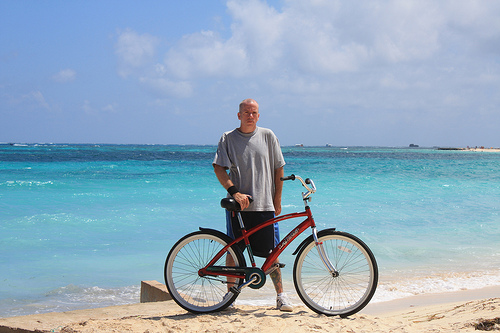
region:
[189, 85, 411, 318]
a man with a bike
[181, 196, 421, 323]
a man with a red bike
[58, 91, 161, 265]
blue bright water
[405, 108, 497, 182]
a island in the backgroudn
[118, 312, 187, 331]
sand on ground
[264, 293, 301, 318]
the shoes for the man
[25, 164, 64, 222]
a little bit of waves in the back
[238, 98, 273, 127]
the man with the bikes face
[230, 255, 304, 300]
the pedals of the bike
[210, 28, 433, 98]
clouds in the back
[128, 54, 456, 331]
man with bicycle at the beach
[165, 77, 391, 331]
white man with bicycle at beach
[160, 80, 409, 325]
blond man with bicycle at beach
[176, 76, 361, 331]
man with red bicycle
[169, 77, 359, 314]
man standing next to bicycle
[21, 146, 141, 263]
beautiful blue ocean water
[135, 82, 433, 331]
riding bicycle on sandy beach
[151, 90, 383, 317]
bicyclist in grey t-shirt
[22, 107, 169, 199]
horizon line where sky meets ocean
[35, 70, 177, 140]
blue sky with some clouds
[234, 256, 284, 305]
Chrome pedals on bike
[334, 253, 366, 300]
Spokes on wheel of bike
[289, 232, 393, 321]
Rubber wheel on bike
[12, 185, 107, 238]
Light blue ocean water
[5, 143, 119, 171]
Deep, dark zone of ocean water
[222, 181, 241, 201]
Black sweat armband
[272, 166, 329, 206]
Handlebars with black handles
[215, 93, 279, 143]
Man with a bald head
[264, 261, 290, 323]
Green tattoo on man's leg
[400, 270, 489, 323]
Water on beach shore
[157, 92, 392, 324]
A man standing beside a red bike.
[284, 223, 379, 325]
A large front bicycle wheel.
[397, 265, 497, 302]
Surf rolling into the beach.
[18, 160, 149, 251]
Blue ocean water.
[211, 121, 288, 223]
A gray T-shirt on the man.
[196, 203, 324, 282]
A red bicycle frame.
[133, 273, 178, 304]
A board protruding from the beach.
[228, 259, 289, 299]
Pedals on the bike.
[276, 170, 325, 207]
Chrome plated bicycle handlebars.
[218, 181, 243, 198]
A wrist band made of black material.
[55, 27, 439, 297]
The sky is blue.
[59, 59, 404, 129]
It is a sunny day.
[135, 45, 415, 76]
The clouds are white.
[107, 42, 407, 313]
A man is next to his bike.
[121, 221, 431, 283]
The bike is red.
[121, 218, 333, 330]
Thetires are white and black.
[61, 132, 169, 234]
The ocean is behind the man.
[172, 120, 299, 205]
The man is wearing a short sleeved shirt.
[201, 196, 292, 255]
The man is wearing shorts.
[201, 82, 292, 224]
The man's hand is on the bike seat.